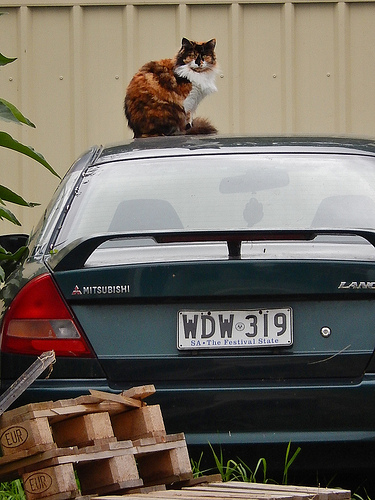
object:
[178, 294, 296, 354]
license plate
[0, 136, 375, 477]
car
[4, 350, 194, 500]
wood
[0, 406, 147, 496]
blocks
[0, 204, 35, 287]
grass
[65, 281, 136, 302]
logo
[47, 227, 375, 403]
trunk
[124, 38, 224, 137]
cat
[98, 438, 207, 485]
pallet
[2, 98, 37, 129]
leaf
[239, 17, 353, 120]
wall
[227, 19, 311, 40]
metal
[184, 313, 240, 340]
letters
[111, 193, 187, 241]
seat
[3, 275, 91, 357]
taillight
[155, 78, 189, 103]
fur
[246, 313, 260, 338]
3